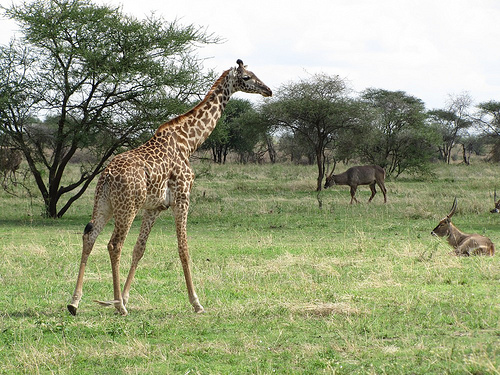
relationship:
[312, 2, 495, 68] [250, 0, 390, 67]
clouds in sky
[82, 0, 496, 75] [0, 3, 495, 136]
cloud in sky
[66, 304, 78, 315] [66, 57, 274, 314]
hoof in giraffe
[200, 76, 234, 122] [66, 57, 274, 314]
neck of giraffe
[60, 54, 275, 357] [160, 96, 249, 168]
giraffe has neck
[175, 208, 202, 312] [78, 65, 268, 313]
leg of giraffe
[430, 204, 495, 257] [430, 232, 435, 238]
animal has nose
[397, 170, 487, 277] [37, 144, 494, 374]
animal sitting in grass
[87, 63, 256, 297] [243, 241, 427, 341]
giraffe standing in grassy area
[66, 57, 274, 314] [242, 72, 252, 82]
giraffe has eye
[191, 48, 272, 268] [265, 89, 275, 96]
giraffe has nose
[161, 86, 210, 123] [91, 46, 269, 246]
hair on neck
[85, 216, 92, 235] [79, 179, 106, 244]
hair on tip of giraffes tail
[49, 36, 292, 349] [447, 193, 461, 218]
animal has horns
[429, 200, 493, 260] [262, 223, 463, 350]
animal resting on grass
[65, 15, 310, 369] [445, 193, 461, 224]
animal has horns